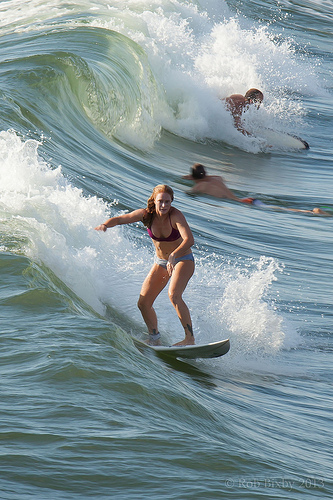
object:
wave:
[0, 0, 333, 500]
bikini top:
[146, 208, 194, 270]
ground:
[277, 125, 301, 159]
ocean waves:
[0, 0, 333, 152]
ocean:
[0, 0, 333, 500]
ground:
[169, 40, 186, 60]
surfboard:
[259, 205, 312, 214]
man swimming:
[163, 162, 333, 217]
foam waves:
[0, 128, 288, 368]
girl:
[93, 184, 195, 347]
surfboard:
[109, 301, 243, 367]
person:
[219, 88, 274, 148]